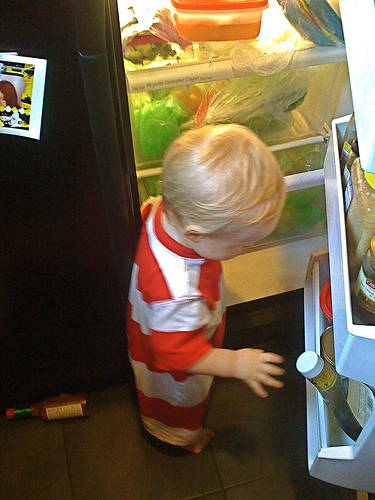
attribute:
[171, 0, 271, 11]
lid — red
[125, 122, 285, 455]
child — young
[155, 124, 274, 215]
hair — blond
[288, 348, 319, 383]
cap — white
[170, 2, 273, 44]
container — plastic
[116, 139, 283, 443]
child — young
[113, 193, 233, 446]
shirt — red, white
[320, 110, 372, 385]
fridge shelf — white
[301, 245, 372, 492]
fridge shelf — white